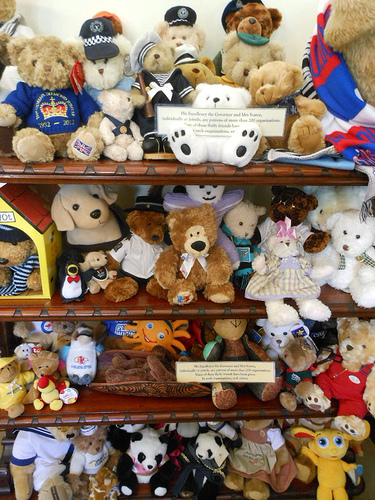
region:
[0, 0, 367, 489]
Shelf with lots of staffed animals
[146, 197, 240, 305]
Teddy bar is brown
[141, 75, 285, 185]
White teddy bears holds a paper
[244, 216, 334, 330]
Plush rabbit has a squared dress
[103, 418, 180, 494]
Panda plush with black ears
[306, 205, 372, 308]
White bear with ribbon in neck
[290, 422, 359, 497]
Yellow plush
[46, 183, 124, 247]
Dog plush with black nose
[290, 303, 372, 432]
Brown plush wearing red overalls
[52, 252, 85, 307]
Penguin stuffed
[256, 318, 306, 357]
white fluffy teddy bear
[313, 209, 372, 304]
white fluffy teddy bear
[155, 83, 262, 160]
white fluffy teddy bear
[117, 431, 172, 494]
white and black fluffy teddy panda bear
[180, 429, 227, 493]
white and black fluffy teddy panda bear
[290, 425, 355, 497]
yellow and red bunny stuffed animal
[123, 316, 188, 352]
orange stuffed sun animal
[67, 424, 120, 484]
brown teddy bear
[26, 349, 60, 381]
brown teddy bear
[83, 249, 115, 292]
brown teddy bear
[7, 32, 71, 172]
a stuffed toy wearing a blue shirt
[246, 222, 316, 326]
a stuffed toy wearing a dress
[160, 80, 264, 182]
a teddy bear holding a sign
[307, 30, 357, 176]
a blue and red scarf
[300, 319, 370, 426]
a teddy bear wearing red coveralls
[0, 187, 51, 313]
a teddy bear in a box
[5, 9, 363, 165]
several toys on a shelf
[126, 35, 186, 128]
a teddy bear wearing a sailor suit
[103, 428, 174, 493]
a black and white toy panda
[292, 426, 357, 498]
a yellow toy with large eyes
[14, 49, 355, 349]
A whole bunch of stuffed animals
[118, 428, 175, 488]
A small panda bear stuff animal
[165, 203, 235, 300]
A brown fluffy teddy bear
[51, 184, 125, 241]
A light beige doggie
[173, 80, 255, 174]
A white polar bear stuff animal in display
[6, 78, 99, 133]
A blue shirt with a royal logo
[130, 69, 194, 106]
A black dress with a white bow tie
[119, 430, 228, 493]
Two pandas are in display together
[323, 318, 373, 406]
A brown teddy bear in red jumpsuit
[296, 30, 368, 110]
A stuff animal with a sporty outfit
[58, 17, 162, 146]
police officer teddy bear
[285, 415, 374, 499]
yellow stuffed toy on shelf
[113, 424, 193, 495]
panda bear stuffed toy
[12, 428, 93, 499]
teddy bear wearing sailor outfit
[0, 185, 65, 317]
yellow and red dog house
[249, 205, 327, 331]
teddy bear wearing a dress and bow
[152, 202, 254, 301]
brown stuffed teddy bear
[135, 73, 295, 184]
white teddy bear holding sign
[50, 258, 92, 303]
little stuffed penguin toy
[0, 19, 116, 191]
teddy bear wearing blue sweater